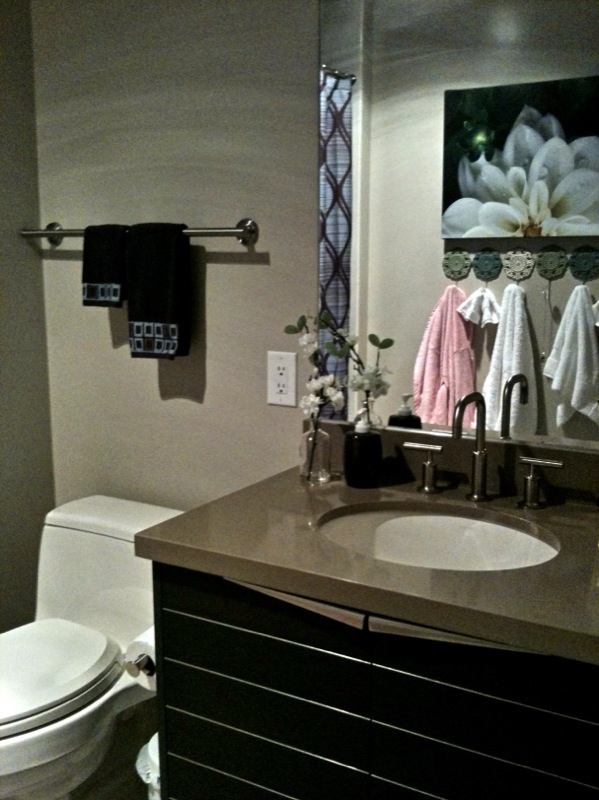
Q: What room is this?
A: It is a bathroom.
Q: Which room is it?
A: It is a bathroom.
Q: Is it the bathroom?
A: Yes, it is the bathroom.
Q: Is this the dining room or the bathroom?
A: It is the bathroom.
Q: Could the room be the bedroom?
A: No, it is the bathroom.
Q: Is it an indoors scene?
A: Yes, it is indoors.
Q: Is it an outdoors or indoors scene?
A: It is indoors.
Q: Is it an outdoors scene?
A: No, it is indoors.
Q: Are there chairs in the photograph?
A: No, there are no chairs.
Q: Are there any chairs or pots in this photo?
A: No, there are no chairs or pots.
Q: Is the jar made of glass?
A: Yes, the jar is made of glass.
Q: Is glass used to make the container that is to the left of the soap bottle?
A: Yes, the jar is made of glass.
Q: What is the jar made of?
A: The jar is made of glass.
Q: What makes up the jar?
A: The jar is made of glass.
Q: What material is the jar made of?
A: The jar is made of glass.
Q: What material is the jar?
A: The jar is made of glass.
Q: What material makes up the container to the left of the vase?
A: The jar is made of glass.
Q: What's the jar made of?
A: The jar is made of glass.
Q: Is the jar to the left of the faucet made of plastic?
A: No, the jar is made of glass.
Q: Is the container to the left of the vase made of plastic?
A: No, the jar is made of glass.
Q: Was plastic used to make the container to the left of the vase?
A: No, the jar is made of glass.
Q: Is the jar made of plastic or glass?
A: The jar is made of glass.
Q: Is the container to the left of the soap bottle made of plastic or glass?
A: The jar is made of glass.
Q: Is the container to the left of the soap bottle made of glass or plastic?
A: The jar is made of glass.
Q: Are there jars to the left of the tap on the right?
A: Yes, there is a jar to the left of the tap.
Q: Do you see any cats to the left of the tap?
A: No, there is a jar to the left of the tap.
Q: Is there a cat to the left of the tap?
A: No, there is a jar to the left of the tap.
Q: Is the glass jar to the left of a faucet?
A: Yes, the jar is to the left of a faucet.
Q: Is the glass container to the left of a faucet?
A: Yes, the jar is to the left of a faucet.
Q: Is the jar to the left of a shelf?
A: No, the jar is to the left of a faucet.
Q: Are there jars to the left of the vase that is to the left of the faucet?
A: Yes, there is a jar to the left of the vase.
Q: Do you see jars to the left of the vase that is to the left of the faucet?
A: Yes, there is a jar to the left of the vase.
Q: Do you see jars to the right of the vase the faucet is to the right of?
A: No, the jar is to the left of the vase.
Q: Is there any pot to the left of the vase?
A: No, there is a jar to the left of the vase.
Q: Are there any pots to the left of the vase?
A: No, there is a jar to the left of the vase.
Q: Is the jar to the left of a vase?
A: Yes, the jar is to the left of a vase.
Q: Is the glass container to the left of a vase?
A: Yes, the jar is to the left of a vase.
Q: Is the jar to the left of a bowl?
A: No, the jar is to the left of a vase.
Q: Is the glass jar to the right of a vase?
A: No, the jar is to the left of a vase.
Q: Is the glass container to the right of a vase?
A: No, the jar is to the left of a vase.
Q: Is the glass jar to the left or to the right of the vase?
A: The jar is to the left of the vase.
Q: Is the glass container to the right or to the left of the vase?
A: The jar is to the left of the vase.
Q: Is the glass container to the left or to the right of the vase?
A: The jar is to the left of the vase.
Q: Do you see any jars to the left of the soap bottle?
A: Yes, there is a jar to the left of the soap bottle.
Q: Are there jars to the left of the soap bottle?
A: Yes, there is a jar to the left of the soap bottle.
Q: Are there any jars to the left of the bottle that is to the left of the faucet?
A: Yes, there is a jar to the left of the soap bottle.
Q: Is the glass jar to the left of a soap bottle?
A: Yes, the jar is to the left of a soap bottle.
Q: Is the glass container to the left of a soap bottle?
A: Yes, the jar is to the left of a soap bottle.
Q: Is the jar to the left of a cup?
A: No, the jar is to the left of a soap bottle.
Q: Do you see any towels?
A: Yes, there is a towel.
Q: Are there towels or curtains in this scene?
A: Yes, there is a towel.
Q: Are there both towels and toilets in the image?
A: Yes, there are both a towel and a toilet.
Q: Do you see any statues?
A: No, there are no statues.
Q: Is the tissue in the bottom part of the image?
A: Yes, the tissue is in the bottom of the image.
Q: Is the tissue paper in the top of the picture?
A: No, the tissue paper is in the bottom of the image.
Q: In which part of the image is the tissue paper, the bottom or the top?
A: The tissue paper is in the bottom of the image.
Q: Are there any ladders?
A: No, there are no ladders.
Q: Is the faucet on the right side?
A: Yes, the faucet is on the right of the image.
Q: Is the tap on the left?
A: No, the tap is on the right of the image.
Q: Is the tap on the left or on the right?
A: The tap is on the right of the image.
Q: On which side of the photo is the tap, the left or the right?
A: The tap is on the right of the image.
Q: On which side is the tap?
A: The tap is on the right of the image.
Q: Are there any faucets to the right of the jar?
A: Yes, there is a faucet to the right of the jar.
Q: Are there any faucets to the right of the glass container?
A: Yes, there is a faucet to the right of the jar.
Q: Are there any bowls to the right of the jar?
A: No, there is a faucet to the right of the jar.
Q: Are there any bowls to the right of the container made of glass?
A: No, there is a faucet to the right of the jar.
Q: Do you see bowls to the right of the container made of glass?
A: No, there is a faucet to the right of the jar.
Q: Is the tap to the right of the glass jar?
A: Yes, the tap is to the right of the jar.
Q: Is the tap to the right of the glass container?
A: Yes, the tap is to the right of the jar.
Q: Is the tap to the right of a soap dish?
A: No, the tap is to the right of the jar.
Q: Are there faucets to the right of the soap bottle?
A: Yes, there is a faucet to the right of the soap bottle.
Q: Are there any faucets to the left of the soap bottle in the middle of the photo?
A: No, the faucet is to the right of the soap bottle.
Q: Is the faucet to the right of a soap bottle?
A: Yes, the faucet is to the right of a soap bottle.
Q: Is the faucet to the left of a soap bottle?
A: No, the faucet is to the right of a soap bottle.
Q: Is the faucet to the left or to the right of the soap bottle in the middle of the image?
A: The faucet is to the right of the soap bottle.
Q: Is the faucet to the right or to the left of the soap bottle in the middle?
A: The faucet is to the right of the soap bottle.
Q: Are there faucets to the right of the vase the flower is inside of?
A: Yes, there is a faucet to the right of the vase.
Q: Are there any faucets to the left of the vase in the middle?
A: No, the faucet is to the right of the vase.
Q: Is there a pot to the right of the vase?
A: No, there is a faucet to the right of the vase.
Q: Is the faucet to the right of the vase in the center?
A: Yes, the faucet is to the right of the vase.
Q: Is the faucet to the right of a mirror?
A: No, the faucet is to the right of the vase.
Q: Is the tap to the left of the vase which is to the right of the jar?
A: No, the tap is to the right of the vase.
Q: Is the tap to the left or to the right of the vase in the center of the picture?
A: The tap is to the right of the vase.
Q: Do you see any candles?
A: No, there are no candles.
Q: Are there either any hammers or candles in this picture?
A: No, there are no candles or hammers.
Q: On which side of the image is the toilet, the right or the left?
A: The toilet is on the left of the image.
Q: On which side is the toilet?
A: The toilet is on the left of the image.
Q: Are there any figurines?
A: No, there are no figurines.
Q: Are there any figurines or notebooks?
A: No, there are no figurines or notebooks.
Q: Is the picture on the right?
A: Yes, the picture is on the right of the image.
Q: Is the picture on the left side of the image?
A: No, the picture is on the right of the image.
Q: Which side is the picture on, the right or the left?
A: The picture is on the right of the image.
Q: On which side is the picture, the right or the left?
A: The picture is on the right of the image.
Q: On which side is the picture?
A: The picture is on the right of the image.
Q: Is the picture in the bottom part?
A: No, the picture is in the top of the image.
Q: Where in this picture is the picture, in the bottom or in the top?
A: The picture is in the top of the image.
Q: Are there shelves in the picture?
A: No, there are no shelves.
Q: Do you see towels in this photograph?
A: Yes, there is a towel.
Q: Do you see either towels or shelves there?
A: Yes, there is a towel.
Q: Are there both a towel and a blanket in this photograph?
A: No, there is a towel but no blankets.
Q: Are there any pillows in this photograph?
A: No, there are no pillows.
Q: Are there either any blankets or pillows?
A: No, there are no pillows or blankets.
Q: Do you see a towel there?
A: Yes, there is a towel.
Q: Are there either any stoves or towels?
A: Yes, there is a towel.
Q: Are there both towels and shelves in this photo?
A: No, there is a towel but no shelves.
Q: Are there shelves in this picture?
A: No, there are no shelves.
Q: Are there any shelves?
A: No, there are no shelves.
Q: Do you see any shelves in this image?
A: No, there are no shelves.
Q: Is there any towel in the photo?
A: Yes, there is a towel.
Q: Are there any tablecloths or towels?
A: Yes, there is a towel.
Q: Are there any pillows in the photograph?
A: No, there are no pillows.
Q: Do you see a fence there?
A: No, there are no fences.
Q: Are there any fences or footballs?
A: No, there are no fences or footballs.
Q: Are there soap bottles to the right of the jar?
A: Yes, there is a soap bottle to the right of the jar.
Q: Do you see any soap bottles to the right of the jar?
A: Yes, there is a soap bottle to the right of the jar.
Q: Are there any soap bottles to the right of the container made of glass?
A: Yes, there is a soap bottle to the right of the jar.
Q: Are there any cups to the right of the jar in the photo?
A: No, there is a soap bottle to the right of the jar.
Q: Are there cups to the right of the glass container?
A: No, there is a soap bottle to the right of the jar.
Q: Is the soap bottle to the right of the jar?
A: Yes, the soap bottle is to the right of the jar.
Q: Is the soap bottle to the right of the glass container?
A: Yes, the soap bottle is to the right of the jar.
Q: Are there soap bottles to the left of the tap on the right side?
A: Yes, there is a soap bottle to the left of the faucet.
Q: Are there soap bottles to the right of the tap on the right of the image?
A: No, the soap bottle is to the left of the faucet.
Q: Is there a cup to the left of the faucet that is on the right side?
A: No, there is a soap bottle to the left of the tap.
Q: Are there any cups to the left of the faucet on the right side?
A: No, there is a soap bottle to the left of the tap.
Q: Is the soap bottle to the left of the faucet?
A: Yes, the soap bottle is to the left of the faucet.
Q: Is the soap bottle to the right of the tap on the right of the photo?
A: No, the soap bottle is to the left of the faucet.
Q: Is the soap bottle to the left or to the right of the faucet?
A: The soap bottle is to the left of the faucet.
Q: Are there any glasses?
A: No, there are no glasses.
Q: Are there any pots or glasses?
A: No, there are no glasses or pots.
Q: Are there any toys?
A: No, there are no toys.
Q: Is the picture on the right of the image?
A: Yes, the picture is on the right of the image.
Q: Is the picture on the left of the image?
A: No, the picture is on the right of the image.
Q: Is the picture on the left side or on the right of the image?
A: The picture is on the right of the image.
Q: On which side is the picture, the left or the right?
A: The picture is on the right of the image.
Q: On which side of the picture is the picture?
A: The picture is on the right of the image.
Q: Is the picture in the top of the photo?
A: Yes, the picture is in the top of the image.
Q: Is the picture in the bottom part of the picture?
A: No, the picture is in the top of the image.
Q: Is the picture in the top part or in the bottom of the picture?
A: The picture is in the top of the image.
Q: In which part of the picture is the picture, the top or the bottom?
A: The picture is in the top of the image.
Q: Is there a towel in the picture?
A: Yes, there is a towel.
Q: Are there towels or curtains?
A: Yes, there is a towel.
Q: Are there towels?
A: Yes, there is a towel.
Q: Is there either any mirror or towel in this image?
A: Yes, there is a towel.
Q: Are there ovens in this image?
A: No, there are no ovens.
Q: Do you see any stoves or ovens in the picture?
A: No, there are no ovens or stoves.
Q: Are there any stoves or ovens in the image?
A: No, there are no ovens or stoves.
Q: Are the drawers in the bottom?
A: Yes, the drawers are in the bottom of the image.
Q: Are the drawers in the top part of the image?
A: No, the drawers are in the bottom of the image.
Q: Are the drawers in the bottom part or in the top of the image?
A: The drawers are in the bottom of the image.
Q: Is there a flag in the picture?
A: No, there are no flags.